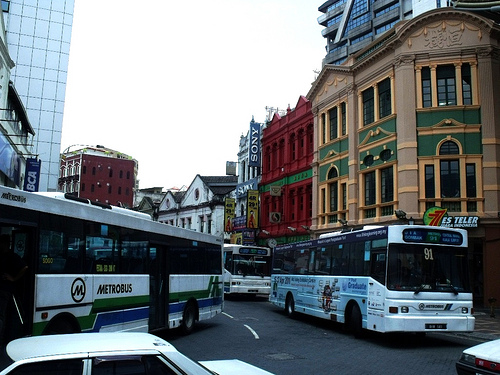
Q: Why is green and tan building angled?
A: On corner.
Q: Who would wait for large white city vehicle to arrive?
A: Bus rider.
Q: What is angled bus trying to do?
A: Turn corner.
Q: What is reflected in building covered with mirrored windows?
A: Sky.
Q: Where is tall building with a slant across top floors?
A: Behind older buildings.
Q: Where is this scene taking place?
A: City street.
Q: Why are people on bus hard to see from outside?
A: Tinted windows.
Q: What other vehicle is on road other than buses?
A: Car.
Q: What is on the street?
A: The buses.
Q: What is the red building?
A: Tall.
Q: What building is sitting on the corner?
A: Green and gold.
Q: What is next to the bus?
A: The white car.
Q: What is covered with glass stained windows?
A: The building.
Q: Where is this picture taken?
A: A street.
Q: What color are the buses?
A: White.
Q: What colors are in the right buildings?
A: Red, green and gold.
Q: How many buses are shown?
A: Three.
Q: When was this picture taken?
A: Daytime.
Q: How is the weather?
A: Clear.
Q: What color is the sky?
A: White.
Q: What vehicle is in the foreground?
A: A car.